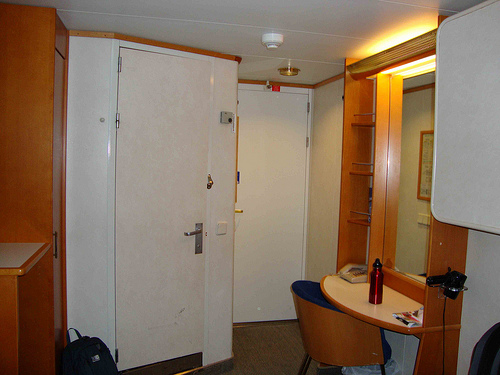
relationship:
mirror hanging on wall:
[399, 74, 436, 280] [302, 52, 499, 364]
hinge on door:
[118, 55, 123, 73] [116, 44, 208, 370]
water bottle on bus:
[369, 255, 384, 307] [16, 33, 496, 371]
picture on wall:
[408, 133, 442, 203] [383, 65, 441, 306]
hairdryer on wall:
[427, 265, 469, 299] [469, 247, 496, 279]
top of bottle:
[369, 259, 385, 267] [368, 256, 386, 306]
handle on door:
[183, 227, 207, 239] [109, 39, 215, 373]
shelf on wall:
[337, 72, 399, 269] [401, 90, 426, 272]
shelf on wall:
[337, 72, 399, 269] [307, 77, 339, 284]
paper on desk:
[393, 301, 428, 325] [395, 305, 417, 327]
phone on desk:
[334, 260, 367, 285] [319, 268, 425, 335]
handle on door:
[164, 212, 222, 261] [81, 40, 253, 373]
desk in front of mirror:
[324, 275, 422, 339] [391, 67, 436, 281]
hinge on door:
[113, 349, 118, 364] [116, 44, 208, 370]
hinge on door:
[115, 112, 120, 127] [116, 44, 208, 370]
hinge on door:
[307, 100, 310, 115] [232, 87, 309, 322]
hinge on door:
[305, 136, 310, 147] [232, 87, 309, 322]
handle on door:
[52, 229, 62, 264] [51, 42, 78, 333]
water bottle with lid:
[369, 257, 384, 305] [370, 258, 383, 268]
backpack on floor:
[57, 324, 125, 373] [176, 320, 332, 373]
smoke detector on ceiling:
[248, 34, 281, 51] [28, 0, 444, 91]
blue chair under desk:
[286, 272, 401, 373] [319, 268, 425, 335]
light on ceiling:
[380, 22, 414, 51] [307, 7, 411, 36]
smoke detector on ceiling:
[259, 34, 283, 50] [317, 19, 371, 40]